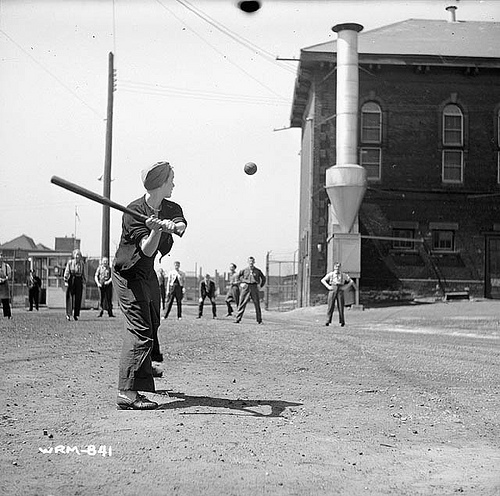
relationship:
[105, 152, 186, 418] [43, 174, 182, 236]
boy holding bat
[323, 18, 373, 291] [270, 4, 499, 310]
pipe by building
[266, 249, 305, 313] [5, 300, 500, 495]
gate of yard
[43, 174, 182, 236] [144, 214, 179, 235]
bat in hands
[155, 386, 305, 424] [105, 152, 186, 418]
shadow of player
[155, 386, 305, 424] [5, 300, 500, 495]
shadow on ground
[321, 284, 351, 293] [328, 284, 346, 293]
hands on hips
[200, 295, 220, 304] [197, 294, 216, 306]
hands on knees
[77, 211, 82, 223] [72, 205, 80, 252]
flag flies flag pole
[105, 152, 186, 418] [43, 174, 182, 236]
kid holding bat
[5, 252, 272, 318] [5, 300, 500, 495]
players in field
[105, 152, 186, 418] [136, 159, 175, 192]
boy wearing hat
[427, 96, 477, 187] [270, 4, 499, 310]
windows on building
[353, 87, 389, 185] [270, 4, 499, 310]
windows on building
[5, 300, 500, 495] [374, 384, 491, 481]
ground has dirt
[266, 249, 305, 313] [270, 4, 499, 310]
fence by building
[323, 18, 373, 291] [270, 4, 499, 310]
silo on building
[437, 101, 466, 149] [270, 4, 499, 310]
window in building